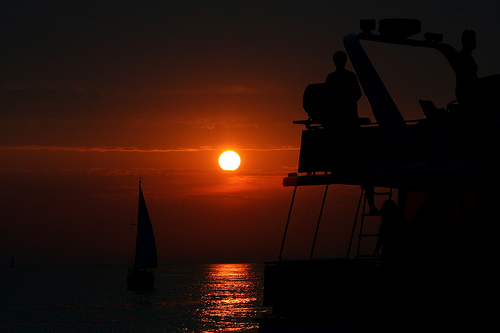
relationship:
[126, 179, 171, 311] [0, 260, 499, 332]
boat on water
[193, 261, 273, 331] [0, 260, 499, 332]
reflection in water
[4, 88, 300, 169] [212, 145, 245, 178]
cloud around sun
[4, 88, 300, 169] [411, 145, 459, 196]
cloud around ground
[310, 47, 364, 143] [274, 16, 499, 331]
people on boat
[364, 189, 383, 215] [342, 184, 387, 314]
leg on ladder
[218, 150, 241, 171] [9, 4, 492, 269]
bright sun in sky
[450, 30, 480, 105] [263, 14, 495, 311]
person standing on boat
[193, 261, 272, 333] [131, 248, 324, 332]
reflection on water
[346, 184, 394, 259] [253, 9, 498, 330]
ladder on boat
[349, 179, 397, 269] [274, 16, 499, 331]
ladder on boat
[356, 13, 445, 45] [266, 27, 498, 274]
lights on boat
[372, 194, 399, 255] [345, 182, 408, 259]
person by ladder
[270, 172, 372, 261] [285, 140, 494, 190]
slanted supports under platform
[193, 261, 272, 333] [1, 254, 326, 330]
reflection on water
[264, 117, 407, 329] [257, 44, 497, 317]
back of a boat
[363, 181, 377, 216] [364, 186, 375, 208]
silhouette of a leg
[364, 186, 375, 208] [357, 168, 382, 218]
leg of a man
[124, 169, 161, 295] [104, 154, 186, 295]
boat of a sailboat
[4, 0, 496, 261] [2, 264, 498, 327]
sunset over a lake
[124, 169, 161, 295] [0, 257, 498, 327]
boat on a lake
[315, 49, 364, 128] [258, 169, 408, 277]
people climbing up ladder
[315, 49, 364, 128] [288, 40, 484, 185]
people on open structure